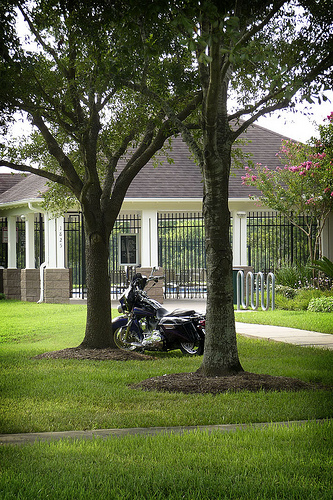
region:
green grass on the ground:
[78, 457, 195, 470]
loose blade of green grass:
[264, 409, 291, 423]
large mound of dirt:
[141, 369, 315, 398]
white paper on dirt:
[161, 369, 167, 373]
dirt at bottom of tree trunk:
[182, 352, 257, 379]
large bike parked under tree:
[113, 267, 204, 353]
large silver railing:
[235, 267, 283, 314]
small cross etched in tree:
[81, 231, 108, 247]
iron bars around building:
[154, 208, 210, 301]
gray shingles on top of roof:
[143, 168, 189, 185]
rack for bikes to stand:
[234, 262, 290, 308]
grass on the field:
[16, 449, 331, 497]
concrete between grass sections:
[6, 420, 317, 442]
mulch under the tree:
[152, 358, 302, 390]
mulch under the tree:
[52, 337, 155, 365]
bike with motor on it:
[108, 288, 224, 349]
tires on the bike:
[103, 309, 205, 354]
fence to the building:
[69, 208, 319, 290]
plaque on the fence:
[112, 232, 144, 265]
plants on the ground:
[289, 286, 330, 314]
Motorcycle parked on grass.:
[104, 265, 209, 356]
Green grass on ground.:
[9, 422, 331, 497]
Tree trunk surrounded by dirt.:
[139, 233, 310, 399]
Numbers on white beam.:
[54, 228, 66, 251]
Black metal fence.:
[156, 227, 216, 299]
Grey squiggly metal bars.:
[235, 268, 279, 313]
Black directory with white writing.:
[118, 233, 139, 269]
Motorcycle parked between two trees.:
[74, 255, 240, 371]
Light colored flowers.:
[288, 272, 329, 297]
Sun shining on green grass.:
[0, 300, 100, 353]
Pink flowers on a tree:
[237, 135, 331, 211]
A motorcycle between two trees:
[1, 24, 331, 376]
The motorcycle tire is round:
[108, 313, 149, 355]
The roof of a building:
[2, 102, 321, 205]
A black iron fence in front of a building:
[0, 209, 332, 298]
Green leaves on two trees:
[1, 1, 331, 219]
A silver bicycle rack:
[230, 266, 277, 313]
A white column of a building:
[132, 209, 162, 267]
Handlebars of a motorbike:
[112, 262, 165, 304]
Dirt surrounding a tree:
[129, 363, 315, 396]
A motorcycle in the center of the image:
[107, 257, 207, 363]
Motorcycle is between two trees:
[1, 1, 332, 395]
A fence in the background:
[1, 211, 332, 299]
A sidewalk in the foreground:
[0, 403, 329, 446]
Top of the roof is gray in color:
[0, 95, 332, 199]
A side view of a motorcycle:
[105, 258, 206, 365]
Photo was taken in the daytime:
[4, 1, 330, 495]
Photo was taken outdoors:
[0, 0, 330, 498]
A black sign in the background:
[116, 228, 139, 266]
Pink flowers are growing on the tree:
[237, 106, 331, 279]